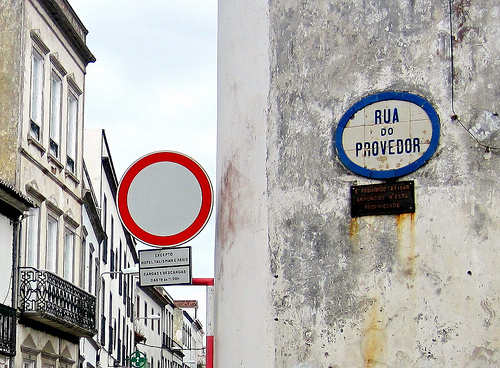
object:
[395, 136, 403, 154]
letter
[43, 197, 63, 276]
window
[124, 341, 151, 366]
sign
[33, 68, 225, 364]
building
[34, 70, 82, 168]
window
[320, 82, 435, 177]
plaque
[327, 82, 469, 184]
words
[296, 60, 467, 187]
sign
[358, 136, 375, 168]
letter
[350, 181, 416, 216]
sign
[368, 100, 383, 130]
letter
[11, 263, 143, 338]
patio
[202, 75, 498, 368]
wall